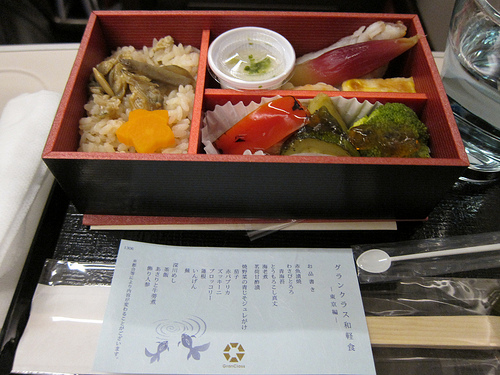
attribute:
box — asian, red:
[42, 10, 471, 220]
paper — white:
[91, 239, 377, 373]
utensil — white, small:
[356, 242, 499, 274]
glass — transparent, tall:
[441, 0, 500, 187]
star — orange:
[116, 108, 177, 154]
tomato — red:
[212, 96, 311, 155]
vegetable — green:
[281, 127, 363, 158]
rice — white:
[74, 36, 201, 153]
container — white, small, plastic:
[207, 26, 297, 89]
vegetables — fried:
[211, 92, 433, 157]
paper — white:
[200, 95, 383, 157]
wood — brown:
[364, 314, 499, 352]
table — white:
[0, 41, 446, 331]